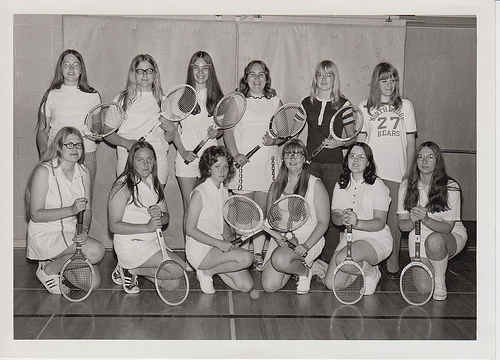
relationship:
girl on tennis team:
[106, 138, 187, 295] [25, 47, 467, 304]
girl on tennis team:
[36, 48, 100, 179] [25, 47, 467, 304]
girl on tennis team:
[177, 53, 216, 180] [25, 47, 467, 304]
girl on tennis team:
[260, 140, 327, 303] [25, 47, 467, 304]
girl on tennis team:
[298, 57, 357, 178] [25, 47, 467, 304]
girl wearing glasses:
[36, 48, 100, 179] [56, 55, 83, 70]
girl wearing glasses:
[303, 57, 345, 162] [416, 148, 441, 161]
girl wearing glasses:
[266, 133, 328, 213] [348, 150, 370, 160]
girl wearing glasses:
[393, 142, 459, 297] [283, 150, 306, 158]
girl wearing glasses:
[328, 140, 392, 294] [318, 69, 335, 81]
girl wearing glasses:
[24, 127, 105, 294] [58, 140, 83, 149]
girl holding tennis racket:
[106, 138, 187, 295] [153, 203, 190, 308]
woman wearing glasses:
[256, 136, 338, 298] [282, 151, 307, 158]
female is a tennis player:
[394, 139, 469, 305] [395, 142, 468, 298]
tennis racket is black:
[235, 100, 307, 170] [268, 115, 292, 141]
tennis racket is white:
[235, 100, 307, 170] [282, 100, 306, 122]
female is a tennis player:
[331, 139, 394, 297] [330, 139, 392, 306]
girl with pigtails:
[260, 138, 330, 292] [268, 137, 308, 221]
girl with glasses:
[260, 138, 330, 292] [283, 150, 306, 158]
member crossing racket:
[256, 137, 333, 299] [266, 192, 311, 249]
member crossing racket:
[182, 145, 260, 296] [220, 195, 273, 243]